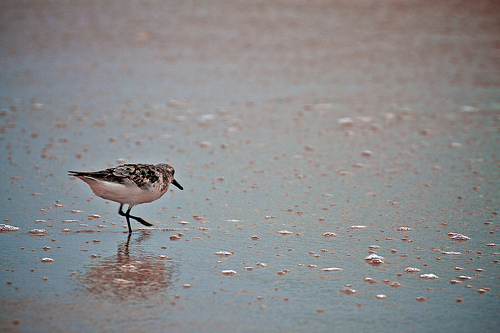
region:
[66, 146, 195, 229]
a bird standing in the water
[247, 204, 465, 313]
bubbles on the surface of the water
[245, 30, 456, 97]
calm brown water of the lake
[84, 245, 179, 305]
reflection of the bird in the water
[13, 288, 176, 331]
brown sand of the beach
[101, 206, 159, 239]
black legs of the bird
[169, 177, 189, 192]
black beak of the bird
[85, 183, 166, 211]
white feathered belly of the bird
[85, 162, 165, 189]
grey and black feathered wings of the bird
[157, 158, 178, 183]
grey and black feathered head of the bird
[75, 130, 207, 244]
bird on the ground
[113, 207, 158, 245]
legs of the bird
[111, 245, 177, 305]
reflection of bird on ground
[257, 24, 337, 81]
blurry background of the photo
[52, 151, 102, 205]
tail feathers of the bird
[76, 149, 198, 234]
dark and light colored bird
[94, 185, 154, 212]
white part of the bird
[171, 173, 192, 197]
beak of the bird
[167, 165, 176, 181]
eye of the bird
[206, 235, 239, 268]
object on the ground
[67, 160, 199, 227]
this is a bird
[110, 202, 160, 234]
these are the bird's feet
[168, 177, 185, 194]
this is a beak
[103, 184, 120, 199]
the bottom is white in color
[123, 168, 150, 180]
the feathers are black in color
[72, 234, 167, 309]
this is the water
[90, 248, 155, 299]
the water has ripples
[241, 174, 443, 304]
these are some objects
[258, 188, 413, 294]
the objects are small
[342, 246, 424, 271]
the objects are white in color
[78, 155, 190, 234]
a bird standing on a beach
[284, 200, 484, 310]
several bubbles on the water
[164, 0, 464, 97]
calm brown water of the lake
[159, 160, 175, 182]
black and grey feathered head of the bird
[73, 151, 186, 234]
a bird standing in the sand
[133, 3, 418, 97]
calm water of the ocean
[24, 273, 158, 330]
wet brown sand of the beach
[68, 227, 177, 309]
the bird's reflection on the water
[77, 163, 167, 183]
black and brown feathers of the birds wings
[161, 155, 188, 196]
brown and black feathered head of the bird